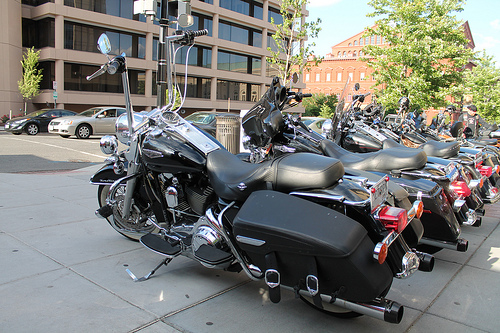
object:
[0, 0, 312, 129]
building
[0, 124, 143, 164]
area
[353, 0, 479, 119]
tree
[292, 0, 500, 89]
sky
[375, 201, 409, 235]
light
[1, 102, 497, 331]
street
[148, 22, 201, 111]
traffic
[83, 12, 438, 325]
motorcycle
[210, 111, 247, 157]
can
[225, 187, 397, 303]
compartment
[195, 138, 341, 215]
seat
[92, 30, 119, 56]
mirror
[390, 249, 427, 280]
plate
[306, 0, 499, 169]
background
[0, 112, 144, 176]
road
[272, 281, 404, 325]
pipe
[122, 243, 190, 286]
stand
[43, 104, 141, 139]
car